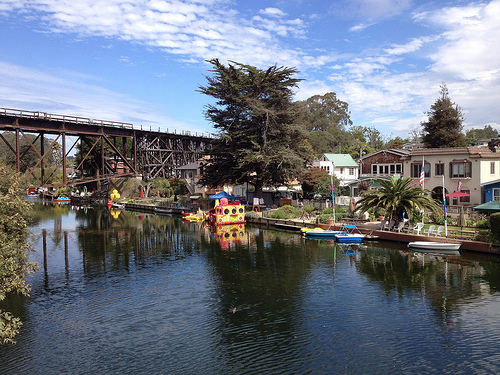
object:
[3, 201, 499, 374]
canal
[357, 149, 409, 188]
house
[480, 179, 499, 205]
house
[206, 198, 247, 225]
boat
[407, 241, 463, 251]
boat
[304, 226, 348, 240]
boat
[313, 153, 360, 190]
house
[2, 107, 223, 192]
bridge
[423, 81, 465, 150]
tree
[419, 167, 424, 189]
flag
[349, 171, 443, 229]
palm tree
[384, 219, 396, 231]
chair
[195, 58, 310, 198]
tree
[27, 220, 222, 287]
reflection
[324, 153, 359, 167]
roof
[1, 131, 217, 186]
substructure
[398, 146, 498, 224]
building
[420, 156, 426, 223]
pole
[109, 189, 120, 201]
object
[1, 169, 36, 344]
tree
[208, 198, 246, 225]
toy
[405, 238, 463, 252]
canoe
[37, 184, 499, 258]
embankment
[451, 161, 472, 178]
window